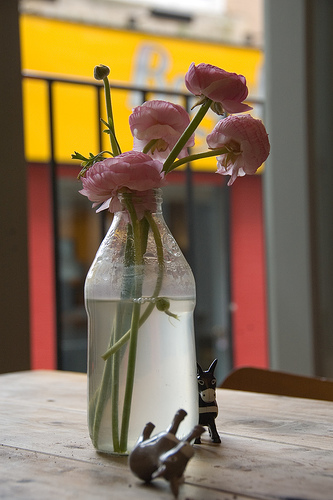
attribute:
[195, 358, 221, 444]
donkey — small, ceramic, toy, plastic, black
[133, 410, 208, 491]
donkey — small, ceramic, toy, brown, plastic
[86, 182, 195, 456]
bottle — glass, clear, transparent, vase, small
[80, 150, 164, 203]
flower — pink, small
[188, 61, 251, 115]
flower — pink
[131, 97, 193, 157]
flower — pink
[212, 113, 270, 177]
flower — pink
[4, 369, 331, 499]
table — wooden, brown, soft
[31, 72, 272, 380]
railing — metal, black, iron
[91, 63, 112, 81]
bud — green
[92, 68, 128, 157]
stem — green, small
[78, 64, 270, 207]
flowers — pink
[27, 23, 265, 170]
wall — yellow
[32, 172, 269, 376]
wall — red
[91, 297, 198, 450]
water — clear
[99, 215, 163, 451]
stems — green, soft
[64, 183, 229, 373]
doors — gray